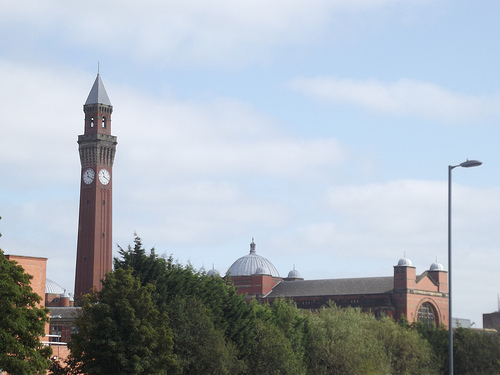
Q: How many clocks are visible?
A: 2.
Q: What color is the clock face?
A: White.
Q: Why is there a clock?
A: Tell time.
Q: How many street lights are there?
A: 1.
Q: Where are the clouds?
A: Sky.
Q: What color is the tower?
A: Red.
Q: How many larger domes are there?
A: 1.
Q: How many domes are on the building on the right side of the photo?
A: Three.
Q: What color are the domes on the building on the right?
A: Silver.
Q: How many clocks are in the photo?
A: Two.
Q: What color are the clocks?
A: Black and white.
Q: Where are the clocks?
A: On sides of tower on the left side of photo.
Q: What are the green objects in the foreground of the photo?
A: Trees.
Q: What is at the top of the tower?
A: Steeple.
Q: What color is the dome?
A: White.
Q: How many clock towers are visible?
A: One.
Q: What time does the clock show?
A: 11:20.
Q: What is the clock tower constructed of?
A: Brick.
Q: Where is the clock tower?
A: Left side.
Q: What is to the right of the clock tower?
A: Dome.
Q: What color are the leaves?
A: Green.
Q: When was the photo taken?
A: Daytime.